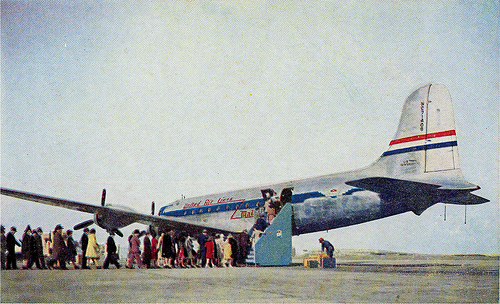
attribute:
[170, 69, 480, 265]
plane — long, large, blue, black, silver, propeller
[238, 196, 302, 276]
stair — blue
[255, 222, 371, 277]
person — lifting, bending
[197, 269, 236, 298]
ground — gray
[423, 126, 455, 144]
tail — red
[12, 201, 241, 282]
people — facing, climbing, walking, lot, getting on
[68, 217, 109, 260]
girl — wearing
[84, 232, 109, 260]
coat — yellow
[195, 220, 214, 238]
man — wearing, loading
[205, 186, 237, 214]
text — red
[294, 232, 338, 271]
man — picking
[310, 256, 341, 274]
luggage — blue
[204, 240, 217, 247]
coat — red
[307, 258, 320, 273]
bag — black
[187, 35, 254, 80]
sky — blue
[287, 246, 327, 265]
table — yellow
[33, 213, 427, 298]
port — air